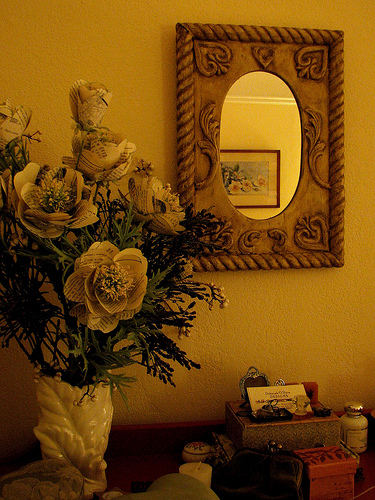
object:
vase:
[33, 369, 113, 499]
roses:
[1, 79, 186, 334]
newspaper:
[74, 249, 147, 332]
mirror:
[175, 23, 345, 273]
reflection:
[220, 149, 281, 209]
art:
[220, 149, 280, 209]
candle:
[178, 462, 212, 490]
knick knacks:
[0, 366, 375, 500]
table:
[0, 408, 374, 499]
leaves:
[0, 77, 233, 413]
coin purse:
[212, 439, 306, 500]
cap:
[344, 400, 364, 418]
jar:
[340, 401, 368, 454]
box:
[292, 445, 356, 500]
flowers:
[184, 441, 207, 451]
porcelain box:
[183, 440, 211, 462]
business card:
[244, 379, 312, 418]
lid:
[291, 444, 357, 480]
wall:
[0, 0, 375, 454]